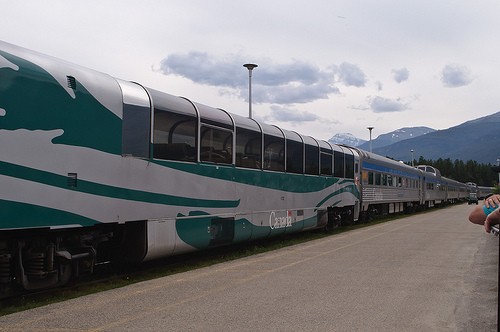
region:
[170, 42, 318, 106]
the sky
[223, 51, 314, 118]
the sky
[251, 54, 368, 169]
the sky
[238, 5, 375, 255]
the sky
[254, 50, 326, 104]
the sky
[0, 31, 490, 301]
The large passenger train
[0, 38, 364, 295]
The portion of the train with green markings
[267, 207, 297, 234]
The name of a country on the train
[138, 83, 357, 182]
The windows on the green train car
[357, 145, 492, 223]
The train cars with a blue stripe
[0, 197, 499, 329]
The platform next to the train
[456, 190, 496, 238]
Diembodied arms and hands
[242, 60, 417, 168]
The lights seen above the train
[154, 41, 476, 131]
The clouds in the sky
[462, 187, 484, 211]
The cart on the walkway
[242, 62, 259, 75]
black metal street light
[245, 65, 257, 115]
black metal street light pole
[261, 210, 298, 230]
writing on side of train engine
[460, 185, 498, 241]
person leaning on guard rail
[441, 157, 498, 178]
row of trees with green leaves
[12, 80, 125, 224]
design on side of train engine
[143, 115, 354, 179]
row of windows on train engine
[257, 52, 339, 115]
white clouds in sky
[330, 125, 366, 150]
mountain top covered in snow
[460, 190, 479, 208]
vehicle driving on street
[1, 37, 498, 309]
a large passenger train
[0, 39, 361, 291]
a green and silver passenger train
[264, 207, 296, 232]
a white Canada train decal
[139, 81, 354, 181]
black tinted windows on the train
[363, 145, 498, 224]
a silver and blue window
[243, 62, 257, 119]
a tall light pole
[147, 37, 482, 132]
puffy clouds in the sky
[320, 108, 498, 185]
a mountainous landscape in the background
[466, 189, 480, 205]
a small cart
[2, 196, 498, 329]
a gravel road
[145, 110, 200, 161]
window on side of train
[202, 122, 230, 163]
window on side of train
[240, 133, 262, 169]
window on side of train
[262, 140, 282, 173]
window on side of train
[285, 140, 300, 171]
window on side of train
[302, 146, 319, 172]
window on side of train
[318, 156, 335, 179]
window on side of train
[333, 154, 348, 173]
window on side of train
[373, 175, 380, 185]
window on side of train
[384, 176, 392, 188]
window on side of train